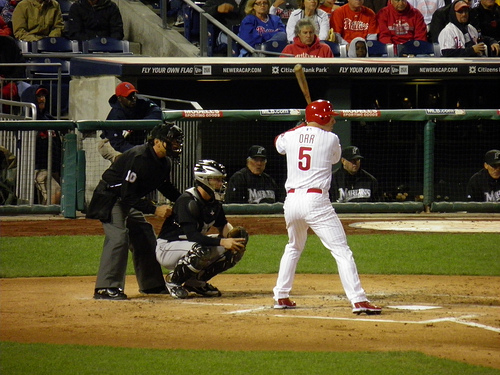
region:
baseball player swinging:
[263, 11, 413, 326]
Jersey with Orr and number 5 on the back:
[242, 91, 355, 208]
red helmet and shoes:
[246, 57, 400, 328]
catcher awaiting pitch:
[171, 152, 257, 293]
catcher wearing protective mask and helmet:
[155, 154, 252, 304]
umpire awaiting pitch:
[89, 95, 189, 309]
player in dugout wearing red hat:
[75, 72, 190, 170]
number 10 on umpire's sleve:
[88, 109, 193, 313]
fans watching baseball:
[0, 3, 495, 80]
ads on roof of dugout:
[96, 27, 494, 104]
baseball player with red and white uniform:
[272, 98, 378, 313]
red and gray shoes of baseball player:
[270, 295, 381, 315]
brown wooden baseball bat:
[294, 63, 314, 112]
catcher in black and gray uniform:
[151, 155, 250, 301]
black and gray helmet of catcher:
[192, 156, 228, 203]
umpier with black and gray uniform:
[86, 123, 188, 301]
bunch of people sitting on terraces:
[221, 2, 499, 67]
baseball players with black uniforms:
[223, 143, 498, 202]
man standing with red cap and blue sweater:
[98, 80, 165, 177]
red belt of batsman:
[281, 185, 330, 193]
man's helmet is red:
[273, 77, 347, 142]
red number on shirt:
[287, 127, 314, 184]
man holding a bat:
[276, 54, 318, 116]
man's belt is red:
[268, 183, 335, 206]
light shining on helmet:
[284, 87, 330, 127]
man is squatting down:
[151, 154, 253, 294]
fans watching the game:
[186, 0, 496, 62]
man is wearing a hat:
[90, 70, 160, 114]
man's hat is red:
[104, 60, 155, 113]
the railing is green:
[0, 103, 499, 215]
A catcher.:
[158, 163, 250, 304]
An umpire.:
[83, 120, 181, 307]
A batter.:
[273, 56, 382, 323]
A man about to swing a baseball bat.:
[254, 54, 384, 322]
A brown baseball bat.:
[292, 60, 315, 107]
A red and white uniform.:
[273, 122, 371, 311]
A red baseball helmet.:
[304, 99, 339, 124]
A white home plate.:
[387, 297, 442, 312]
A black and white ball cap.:
[247, 144, 271, 159]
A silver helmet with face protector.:
[195, 161, 229, 201]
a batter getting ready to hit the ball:
[271, 62, 379, 312]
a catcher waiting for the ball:
[154, 158, 248, 299]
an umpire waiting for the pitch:
[81, 120, 185, 295]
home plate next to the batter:
[387, 301, 442, 311]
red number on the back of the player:
[297, 143, 312, 173]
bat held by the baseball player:
[294, 60, 311, 104]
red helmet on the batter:
[305, 98, 340, 121]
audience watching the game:
[1, 0, 498, 65]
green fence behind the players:
[1, 104, 498, 217]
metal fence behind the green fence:
[0, 92, 202, 206]